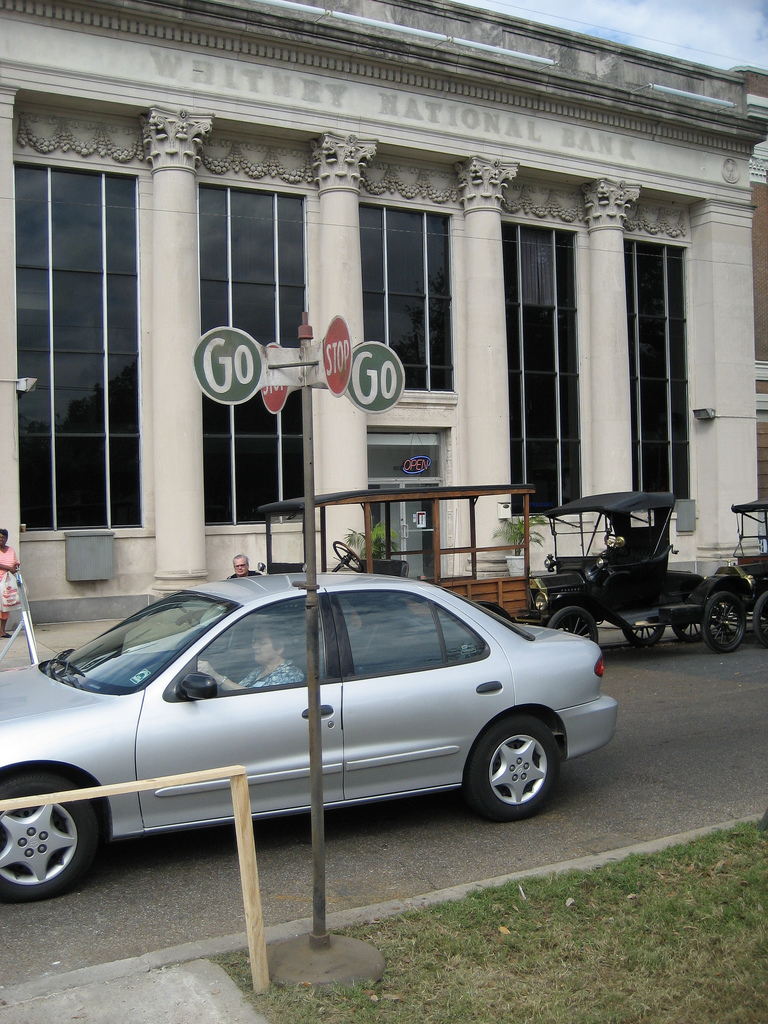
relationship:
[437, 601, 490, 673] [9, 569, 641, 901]
window on car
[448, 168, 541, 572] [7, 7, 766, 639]
column in front of building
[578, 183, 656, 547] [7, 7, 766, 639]
column in front of building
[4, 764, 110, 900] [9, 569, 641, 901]
wheel of car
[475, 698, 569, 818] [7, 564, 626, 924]
wheel of car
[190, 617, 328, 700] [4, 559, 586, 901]
driver in a car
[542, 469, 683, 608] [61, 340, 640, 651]
antique car in front of building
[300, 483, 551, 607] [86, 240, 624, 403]
antique wagon in front of building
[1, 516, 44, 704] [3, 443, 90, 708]
bag bag in hands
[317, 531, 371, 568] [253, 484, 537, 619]
steering wheel on antique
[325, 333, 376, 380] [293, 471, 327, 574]
street sign on pole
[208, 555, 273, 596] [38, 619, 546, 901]
man beside car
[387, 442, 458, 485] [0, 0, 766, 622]
neon sign in building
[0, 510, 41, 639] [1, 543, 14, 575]
woman in a pink dress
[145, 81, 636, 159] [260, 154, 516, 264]
whitney national bank signage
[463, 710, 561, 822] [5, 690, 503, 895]
wheel wheels of a car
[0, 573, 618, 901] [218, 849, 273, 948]
car small wooden fence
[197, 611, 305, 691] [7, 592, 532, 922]
driver lady driving a car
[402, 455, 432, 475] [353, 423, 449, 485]
neon sign behind a pane of glass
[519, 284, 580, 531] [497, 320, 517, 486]
large window panes with white frame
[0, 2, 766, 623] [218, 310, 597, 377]
building wall on side of a building